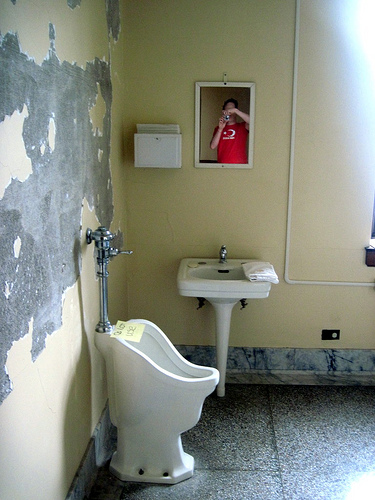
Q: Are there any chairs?
A: No, there are no chairs.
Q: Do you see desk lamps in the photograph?
A: No, there are no desk lamps.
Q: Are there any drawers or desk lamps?
A: No, there are no desk lamps or drawers.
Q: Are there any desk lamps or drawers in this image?
A: No, there are no desk lamps or drawers.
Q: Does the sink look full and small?
A: No, the sink is small but empty.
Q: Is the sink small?
A: Yes, the sink is small.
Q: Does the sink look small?
A: Yes, the sink is small.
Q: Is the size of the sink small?
A: Yes, the sink is small.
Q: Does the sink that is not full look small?
A: Yes, the sink is small.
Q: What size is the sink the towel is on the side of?
A: The sink is small.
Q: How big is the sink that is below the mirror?
A: The sink is small.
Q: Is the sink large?
A: No, the sink is small.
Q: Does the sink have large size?
A: No, the sink is small.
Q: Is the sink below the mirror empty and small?
A: Yes, the sink is empty and small.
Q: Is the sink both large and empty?
A: No, the sink is empty but small.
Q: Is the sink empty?
A: Yes, the sink is empty.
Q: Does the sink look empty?
A: Yes, the sink is empty.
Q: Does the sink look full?
A: No, the sink is empty.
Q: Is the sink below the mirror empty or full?
A: The sink is empty.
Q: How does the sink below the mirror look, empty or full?
A: The sink is empty.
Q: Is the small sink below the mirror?
A: Yes, the sink is below the mirror.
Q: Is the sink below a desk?
A: No, the sink is below the mirror.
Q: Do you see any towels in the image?
A: Yes, there is a towel.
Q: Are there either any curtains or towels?
A: Yes, there is a towel.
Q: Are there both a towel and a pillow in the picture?
A: No, there is a towel but no pillows.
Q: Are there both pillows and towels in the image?
A: No, there is a towel but no pillows.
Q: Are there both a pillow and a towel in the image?
A: No, there is a towel but no pillows.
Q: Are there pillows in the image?
A: No, there are no pillows.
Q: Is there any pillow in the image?
A: No, there are no pillows.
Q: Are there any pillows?
A: No, there are no pillows.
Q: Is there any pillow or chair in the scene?
A: No, there are no pillows or chairs.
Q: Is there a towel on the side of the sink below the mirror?
A: Yes, there is a towel on the side of the sink.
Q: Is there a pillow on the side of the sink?
A: No, there is a towel on the side of the sink.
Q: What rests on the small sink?
A: The towel rests on the sink.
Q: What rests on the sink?
A: The towel rests on the sink.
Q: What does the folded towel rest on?
A: The towel rests on the sink.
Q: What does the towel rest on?
A: The towel rests on the sink.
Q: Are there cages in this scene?
A: No, there are no cages.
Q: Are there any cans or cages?
A: No, there are no cages or cans.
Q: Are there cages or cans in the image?
A: No, there are no cages or cans.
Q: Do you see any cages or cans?
A: No, there are no cages or cans.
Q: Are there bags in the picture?
A: No, there are no bags.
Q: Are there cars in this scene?
A: No, there are no cars.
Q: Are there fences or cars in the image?
A: No, there are no cars or fences.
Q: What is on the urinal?
A: The sign is on the urinal.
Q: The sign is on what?
A: The sign is on the urinal.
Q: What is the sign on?
A: The sign is on the urinal.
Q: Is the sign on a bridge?
A: No, the sign is on a urinal.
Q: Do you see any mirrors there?
A: Yes, there is a mirror.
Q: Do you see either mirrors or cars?
A: Yes, there is a mirror.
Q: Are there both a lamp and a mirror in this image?
A: No, there is a mirror but no lamps.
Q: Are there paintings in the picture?
A: No, there are no paintings.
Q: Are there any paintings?
A: No, there are no paintings.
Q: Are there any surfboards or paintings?
A: No, there are no paintings or surfboards.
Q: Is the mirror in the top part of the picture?
A: Yes, the mirror is in the top of the image.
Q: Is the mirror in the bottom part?
A: No, the mirror is in the top of the image.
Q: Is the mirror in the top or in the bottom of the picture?
A: The mirror is in the top of the image.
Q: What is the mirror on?
A: The mirror is on the wall.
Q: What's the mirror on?
A: The mirror is on the wall.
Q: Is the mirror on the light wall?
A: Yes, the mirror is on the wall.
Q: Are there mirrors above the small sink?
A: Yes, there is a mirror above the sink.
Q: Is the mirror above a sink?
A: Yes, the mirror is above a sink.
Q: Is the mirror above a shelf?
A: No, the mirror is above a sink.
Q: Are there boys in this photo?
A: No, there are no boys.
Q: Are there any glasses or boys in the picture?
A: No, there are no boys or glasses.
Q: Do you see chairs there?
A: No, there are no chairs.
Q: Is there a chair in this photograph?
A: No, there are no chairs.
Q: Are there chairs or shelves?
A: No, there are no chairs or shelves.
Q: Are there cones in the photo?
A: No, there are no cones.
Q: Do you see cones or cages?
A: No, there are no cones or cages.